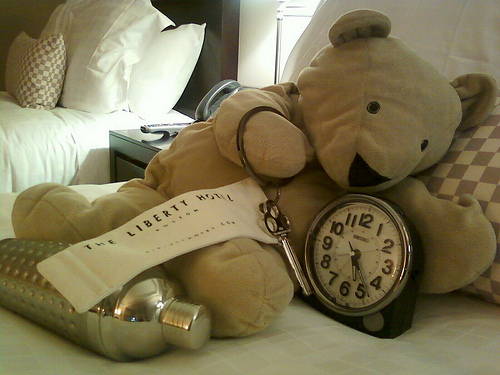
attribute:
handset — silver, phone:
[190, 77, 239, 126]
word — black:
[78, 235, 117, 250]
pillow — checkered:
[3, 30, 66, 110]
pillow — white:
[40, 1, 175, 113]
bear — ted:
[19, 14, 493, 319]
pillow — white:
[133, 19, 210, 120]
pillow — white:
[47, 7, 172, 111]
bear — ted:
[184, 46, 488, 223]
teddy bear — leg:
[99, 11, 480, 303]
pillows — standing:
[2, 2, 214, 131]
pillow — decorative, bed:
[4, 27, 68, 112]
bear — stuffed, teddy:
[62, 22, 499, 346]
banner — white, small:
[35, 180, 281, 311]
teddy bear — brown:
[8, 5, 499, 341]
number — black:
[369, 272, 387, 292]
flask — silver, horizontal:
[1, 235, 218, 365]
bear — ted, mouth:
[12, 7, 498, 360]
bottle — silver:
[1, 232, 216, 368]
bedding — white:
[7, 6, 210, 226]